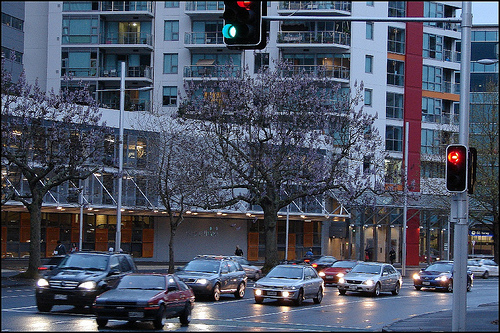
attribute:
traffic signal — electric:
[217, 3, 268, 53]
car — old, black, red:
[93, 267, 203, 332]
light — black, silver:
[437, 130, 473, 208]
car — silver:
[332, 258, 409, 297]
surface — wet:
[0, 273, 497, 330]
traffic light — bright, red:
[443, 143, 468, 194]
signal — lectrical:
[436, 139, 488, 204]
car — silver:
[248, 251, 346, 323]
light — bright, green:
[200, 3, 253, 48]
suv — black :
[31, 246, 138, 311]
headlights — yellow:
[255, 287, 293, 298]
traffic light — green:
[216, 20, 278, 62]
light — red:
[431, 128, 479, 206]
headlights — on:
[28, 274, 102, 293]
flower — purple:
[84, 95, 94, 105]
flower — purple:
[33, 77, 42, 94]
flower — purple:
[94, 111, 102, 122]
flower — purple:
[22, 80, 36, 95]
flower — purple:
[60, 112, 74, 125]